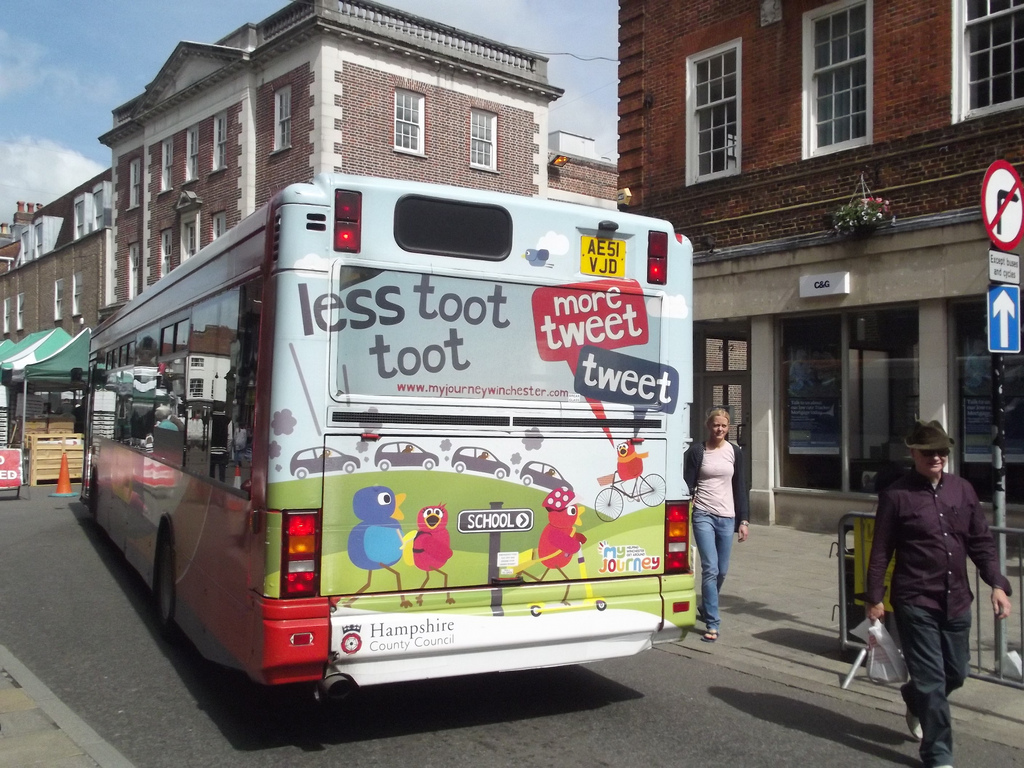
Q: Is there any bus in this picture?
A: Yes, there is a bus.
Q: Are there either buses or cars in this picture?
A: Yes, there is a bus.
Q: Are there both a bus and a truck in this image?
A: No, there is a bus but no trucks.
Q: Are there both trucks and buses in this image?
A: No, there is a bus but no trucks.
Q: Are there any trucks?
A: No, there are no trucks.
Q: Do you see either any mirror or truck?
A: No, there are no trucks or mirrors.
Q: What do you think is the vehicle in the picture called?
A: The vehicle is a bus.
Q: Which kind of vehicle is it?
A: The vehicle is a bus.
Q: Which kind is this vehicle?
A: This is a bus.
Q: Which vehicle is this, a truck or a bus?
A: This is a bus.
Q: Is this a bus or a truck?
A: This is a bus.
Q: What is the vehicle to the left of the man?
A: The vehicle is a bus.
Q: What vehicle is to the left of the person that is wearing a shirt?
A: The vehicle is a bus.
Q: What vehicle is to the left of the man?
A: The vehicle is a bus.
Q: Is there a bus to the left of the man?
A: Yes, there is a bus to the left of the man.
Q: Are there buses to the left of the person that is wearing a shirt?
A: Yes, there is a bus to the left of the man.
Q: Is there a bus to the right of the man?
A: No, the bus is to the left of the man.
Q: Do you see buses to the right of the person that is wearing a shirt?
A: No, the bus is to the left of the man.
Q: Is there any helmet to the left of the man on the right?
A: No, there is a bus to the left of the man.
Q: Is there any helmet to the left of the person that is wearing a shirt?
A: No, there is a bus to the left of the man.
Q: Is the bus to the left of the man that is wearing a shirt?
A: Yes, the bus is to the left of the man.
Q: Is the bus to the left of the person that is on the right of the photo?
A: Yes, the bus is to the left of the man.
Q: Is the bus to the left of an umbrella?
A: No, the bus is to the left of the man.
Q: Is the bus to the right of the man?
A: No, the bus is to the left of the man.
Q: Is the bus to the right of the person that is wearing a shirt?
A: No, the bus is to the left of the man.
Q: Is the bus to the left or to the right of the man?
A: The bus is to the left of the man.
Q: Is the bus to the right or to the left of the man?
A: The bus is to the left of the man.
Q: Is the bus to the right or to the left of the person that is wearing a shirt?
A: The bus is to the left of the man.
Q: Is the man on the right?
A: Yes, the man is on the right of the image.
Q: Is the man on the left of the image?
A: No, the man is on the right of the image.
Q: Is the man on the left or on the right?
A: The man is on the right of the image.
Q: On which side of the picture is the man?
A: The man is on the right of the image.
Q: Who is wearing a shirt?
A: The man is wearing a shirt.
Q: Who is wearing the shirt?
A: The man is wearing a shirt.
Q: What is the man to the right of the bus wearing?
A: The man is wearing a shirt.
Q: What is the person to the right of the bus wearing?
A: The man is wearing a shirt.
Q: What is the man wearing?
A: The man is wearing a shirt.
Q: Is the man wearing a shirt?
A: Yes, the man is wearing a shirt.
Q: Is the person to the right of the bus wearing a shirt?
A: Yes, the man is wearing a shirt.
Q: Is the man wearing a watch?
A: No, the man is wearing a shirt.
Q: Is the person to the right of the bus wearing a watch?
A: No, the man is wearing a shirt.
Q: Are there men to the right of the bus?
A: Yes, there is a man to the right of the bus.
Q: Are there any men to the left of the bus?
A: No, the man is to the right of the bus.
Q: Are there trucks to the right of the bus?
A: No, there is a man to the right of the bus.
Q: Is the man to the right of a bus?
A: Yes, the man is to the right of a bus.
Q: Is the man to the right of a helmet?
A: No, the man is to the right of a bus.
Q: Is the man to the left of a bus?
A: No, the man is to the right of a bus.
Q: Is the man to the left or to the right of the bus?
A: The man is to the right of the bus.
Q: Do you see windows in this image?
A: Yes, there is a window.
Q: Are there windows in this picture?
A: Yes, there is a window.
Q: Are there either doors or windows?
A: Yes, there is a window.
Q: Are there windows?
A: Yes, there is a window.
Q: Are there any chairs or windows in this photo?
A: Yes, there is a window.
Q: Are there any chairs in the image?
A: No, there are no chairs.